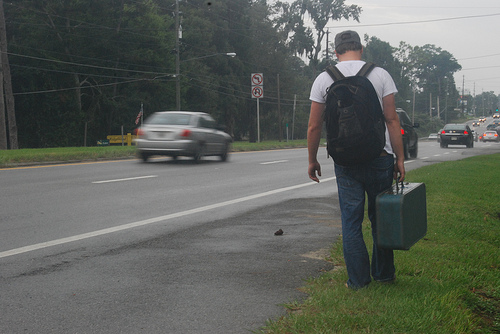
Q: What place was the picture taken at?
A: It was taken at the road.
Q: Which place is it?
A: It is a road.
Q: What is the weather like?
A: It is overcast.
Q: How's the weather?
A: It is overcast.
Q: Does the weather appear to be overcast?
A: Yes, it is overcast.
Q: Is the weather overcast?
A: Yes, it is overcast.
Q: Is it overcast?
A: Yes, it is overcast.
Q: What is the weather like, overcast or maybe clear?
A: It is overcast.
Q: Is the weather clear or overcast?
A: It is overcast.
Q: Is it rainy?
A: No, it is overcast.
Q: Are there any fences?
A: No, there are no fences.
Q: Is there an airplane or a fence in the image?
A: No, there are no fences or airplanes.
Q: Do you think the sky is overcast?
A: Yes, the sky is overcast.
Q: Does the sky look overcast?
A: Yes, the sky is overcast.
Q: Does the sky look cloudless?
A: No, the sky is overcast.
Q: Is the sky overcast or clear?
A: The sky is overcast.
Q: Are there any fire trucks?
A: No, there are no fire trucks.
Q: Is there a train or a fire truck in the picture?
A: No, there are no fire trucks or trains.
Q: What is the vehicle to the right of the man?
A: The vehicle is a car.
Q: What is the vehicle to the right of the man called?
A: The vehicle is a car.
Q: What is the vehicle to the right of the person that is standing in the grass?
A: The vehicle is a car.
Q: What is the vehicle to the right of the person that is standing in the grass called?
A: The vehicle is a car.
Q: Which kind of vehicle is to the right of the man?
A: The vehicle is a car.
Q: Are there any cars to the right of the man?
A: Yes, there is a car to the right of the man.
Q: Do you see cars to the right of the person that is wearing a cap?
A: Yes, there is a car to the right of the man.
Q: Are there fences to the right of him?
A: No, there is a car to the right of the man.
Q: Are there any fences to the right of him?
A: No, there is a car to the right of the man.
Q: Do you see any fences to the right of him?
A: No, there is a car to the right of the man.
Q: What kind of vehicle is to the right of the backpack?
A: The vehicle is a car.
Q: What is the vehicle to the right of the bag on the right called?
A: The vehicle is a car.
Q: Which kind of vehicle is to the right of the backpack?
A: The vehicle is a car.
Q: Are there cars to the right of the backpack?
A: Yes, there is a car to the right of the backpack.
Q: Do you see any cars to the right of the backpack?
A: Yes, there is a car to the right of the backpack.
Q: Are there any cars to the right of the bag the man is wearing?
A: Yes, there is a car to the right of the backpack.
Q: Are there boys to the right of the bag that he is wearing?
A: No, there is a car to the right of the backpack.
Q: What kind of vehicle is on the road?
A: The vehicle is a car.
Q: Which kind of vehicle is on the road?
A: The vehicle is a car.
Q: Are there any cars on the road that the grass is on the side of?
A: Yes, there is a car on the road.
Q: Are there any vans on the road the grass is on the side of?
A: No, there is a car on the road.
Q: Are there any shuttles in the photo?
A: No, there are no shuttles.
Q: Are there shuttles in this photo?
A: No, there are no shuttles.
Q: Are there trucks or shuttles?
A: No, there are no shuttles or trucks.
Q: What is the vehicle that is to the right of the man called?
A: The vehicle is a car.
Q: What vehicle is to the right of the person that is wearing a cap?
A: The vehicle is a car.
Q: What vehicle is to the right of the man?
A: The vehicle is a car.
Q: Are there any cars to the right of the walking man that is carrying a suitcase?
A: Yes, there is a car to the right of the man.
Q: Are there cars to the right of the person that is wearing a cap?
A: Yes, there is a car to the right of the man.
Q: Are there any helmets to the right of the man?
A: No, there is a car to the right of the man.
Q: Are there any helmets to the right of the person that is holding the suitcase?
A: No, there is a car to the right of the man.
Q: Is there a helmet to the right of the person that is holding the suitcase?
A: No, there is a car to the right of the man.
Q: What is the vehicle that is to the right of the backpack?
A: The vehicle is a car.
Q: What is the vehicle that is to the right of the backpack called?
A: The vehicle is a car.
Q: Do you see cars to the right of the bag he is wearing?
A: Yes, there is a car to the right of the backpack.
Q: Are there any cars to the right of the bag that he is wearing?
A: Yes, there is a car to the right of the backpack.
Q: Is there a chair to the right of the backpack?
A: No, there is a car to the right of the backpack.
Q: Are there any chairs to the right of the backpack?
A: No, there is a car to the right of the backpack.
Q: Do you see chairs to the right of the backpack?
A: No, there is a car to the right of the backpack.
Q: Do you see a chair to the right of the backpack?
A: No, there is a car to the right of the backpack.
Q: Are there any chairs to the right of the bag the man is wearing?
A: No, there is a car to the right of the backpack.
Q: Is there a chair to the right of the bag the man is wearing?
A: No, there is a car to the right of the backpack.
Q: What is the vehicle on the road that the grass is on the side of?
A: The vehicle is a car.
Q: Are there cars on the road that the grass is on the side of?
A: Yes, there is a car on the road.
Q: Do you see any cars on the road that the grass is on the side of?
A: Yes, there is a car on the road.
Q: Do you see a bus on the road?
A: No, there is a car on the road.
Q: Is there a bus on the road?
A: No, there is a car on the road.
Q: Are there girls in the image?
A: No, there are no girls.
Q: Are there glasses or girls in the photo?
A: No, there are no girls or glasses.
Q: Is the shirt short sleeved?
A: Yes, the shirt is short sleeved.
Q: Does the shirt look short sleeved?
A: Yes, the shirt is short sleeved.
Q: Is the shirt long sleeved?
A: No, the shirt is short sleeved.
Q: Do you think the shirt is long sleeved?
A: No, the shirt is short sleeved.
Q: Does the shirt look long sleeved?
A: No, the shirt is short sleeved.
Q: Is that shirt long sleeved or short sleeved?
A: The shirt is short sleeved.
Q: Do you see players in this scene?
A: No, there are no players.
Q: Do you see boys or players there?
A: No, there are no players or boys.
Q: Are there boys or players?
A: No, there are no players or boys.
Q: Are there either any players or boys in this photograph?
A: No, there are no players or boys.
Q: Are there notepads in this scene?
A: No, there are no notepads.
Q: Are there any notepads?
A: No, there are no notepads.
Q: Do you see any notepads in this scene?
A: No, there are no notepads.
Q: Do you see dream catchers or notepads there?
A: No, there are no notepads or dream catchers.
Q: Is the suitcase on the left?
A: No, the suitcase is on the right of the image.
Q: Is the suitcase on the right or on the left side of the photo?
A: The suitcase is on the right of the image.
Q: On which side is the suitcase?
A: The suitcase is on the right of the image.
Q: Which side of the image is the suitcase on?
A: The suitcase is on the right of the image.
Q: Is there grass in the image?
A: Yes, there is grass.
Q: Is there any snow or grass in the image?
A: Yes, there is grass.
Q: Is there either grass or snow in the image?
A: Yes, there is grass.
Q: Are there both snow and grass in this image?
A: No, there is grass but no snow.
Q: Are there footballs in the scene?
A: No, there are no footballs.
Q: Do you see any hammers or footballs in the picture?
A: No, there are no footballs or hammers.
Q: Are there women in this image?
A: No, there are no women.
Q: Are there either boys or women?
A: No, there are no women or boys.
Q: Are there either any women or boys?
A: No, there are no women or boys.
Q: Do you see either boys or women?
A: No, there are no women or boys.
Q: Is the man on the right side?
A: Yes, the man is on the right of the image.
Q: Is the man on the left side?
A: No, the man is on the right of the image.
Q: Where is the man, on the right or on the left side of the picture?
A: The man is on the right of the image.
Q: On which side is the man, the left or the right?
A: The man is on the right of the image.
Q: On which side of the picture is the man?
A: The man is on the right of the image.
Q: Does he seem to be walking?
A: Yes, the man is walking.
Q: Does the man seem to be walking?
A: Yes, the man is walking.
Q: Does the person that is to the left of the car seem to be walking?
A: Yes, the man is walking.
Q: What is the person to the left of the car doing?
A: The man is walking.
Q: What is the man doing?
A: The man is walking.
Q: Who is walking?
A: The man is walking.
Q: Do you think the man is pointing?
A: No, the man is walking.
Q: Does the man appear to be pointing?
A: No, the man is walking.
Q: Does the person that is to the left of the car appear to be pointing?
A: No, the man is walking.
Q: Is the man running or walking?
A: The man is walking.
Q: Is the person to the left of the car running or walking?
A: The man is walking.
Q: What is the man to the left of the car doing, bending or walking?
A: The man is walking.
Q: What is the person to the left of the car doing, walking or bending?
A: The man is walking.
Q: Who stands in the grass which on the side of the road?
A: The man stands in the grass.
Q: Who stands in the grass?
A: The man stands in the grass.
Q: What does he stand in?
A: The man stands in the grass.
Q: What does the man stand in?
A: The man stands in the grass.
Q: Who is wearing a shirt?
A: The man is wearing a shirt.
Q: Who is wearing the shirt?
A: The man is wearing a shirt.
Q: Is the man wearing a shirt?
A: Yes, the man is wearing a shirt.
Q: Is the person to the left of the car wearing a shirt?
A: Yes, the man is wearing a shirt.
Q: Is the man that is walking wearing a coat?
A: No, the man is wearing a shirt.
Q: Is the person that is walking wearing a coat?
A: No, the man is wearing a shirt.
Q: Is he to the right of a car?
A: No, the man is to the left of a car.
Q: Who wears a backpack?
A: The man wears a backpack.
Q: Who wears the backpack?
A: The man wears a backpack.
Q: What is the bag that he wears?
A: The bag is a backpack.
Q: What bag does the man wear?
A: The man wears a backpack.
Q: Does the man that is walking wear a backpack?
A: Yes, the man wears a backpack.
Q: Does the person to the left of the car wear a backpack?
A: Yes, the man wears a backpack.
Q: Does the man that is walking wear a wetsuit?
A: No, the man wears a backpack.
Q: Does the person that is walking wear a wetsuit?
A: No, the man wears a backpack.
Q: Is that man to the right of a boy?
A: No, the man is to the right of the car.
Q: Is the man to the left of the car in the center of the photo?
A: No, the man is to the right of the car.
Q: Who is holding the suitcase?
A: The man is holding the suitcase.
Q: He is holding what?
A: The man is holding the suitcase.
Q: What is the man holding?
A: The man is holding the suitcase.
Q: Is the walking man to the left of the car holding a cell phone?
A: No, the man is holding the suitcase.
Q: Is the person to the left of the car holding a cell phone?
A: No, the man is holding the suitcase.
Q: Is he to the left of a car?
A: Yes, the man is to the left of a car.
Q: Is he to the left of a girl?
A: No, the man is to the left of a car.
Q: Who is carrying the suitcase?
A: The man is carrying the suitcase.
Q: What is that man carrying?
A: The man is carrying a suitcase.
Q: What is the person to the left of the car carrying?
A: The man is carrying a suitcase.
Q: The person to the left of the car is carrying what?
A: The man is carrying a suitcase.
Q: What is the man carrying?
A: The man is carrying a suitcase.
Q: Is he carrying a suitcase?
A: Yes, the man is carrying a suitcase.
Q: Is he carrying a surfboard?
A: No, the man is carrying a suitcase.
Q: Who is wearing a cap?
A: The man is wearing a cap.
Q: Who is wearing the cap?
A: The man is wearing a cap.